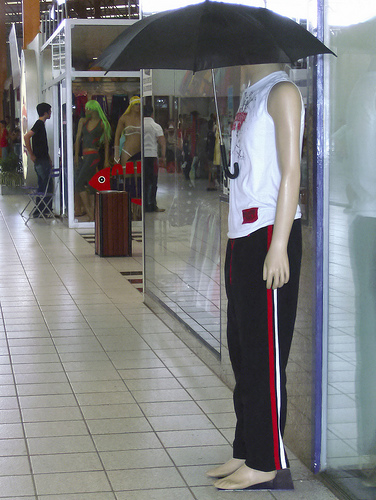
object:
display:
[245, 467, 294, 490]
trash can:
[89, 185, 135, 260]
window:
[61, 102, 68, 217]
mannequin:
[75, 100, 112, 222]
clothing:
[76, 116, 105, 195]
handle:
[220, 144, 239, 179]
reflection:
[144, 106, 165, 211]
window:
[139, 58, 242, 366]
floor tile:
[75, 391, 136, 404]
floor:
[0, 187, 349, 499]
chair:
[20, 166, 61, 225]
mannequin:
[208, 65, 308, 495]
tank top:
[225, 69, 306, 239]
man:
[23, 102, 52, 214]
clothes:
[31, 119, 54, 214]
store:
[147, 0, 375, 478]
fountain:
[93, 188, 131, 257]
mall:
[0, 0, 376, 499]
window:
[71, 77, 141, 223]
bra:
[123, 126, 141, 136]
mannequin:
[113, 96, 144, 212]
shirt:
[31, 119, 49, 160]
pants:
[224, 210, 302, 472]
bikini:
[119, 125, 141, 157]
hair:
[85, 100, 112, 144]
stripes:
[264, 222, 290, 474]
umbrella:
[95, 0, 337, 180]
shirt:
[227, 70, 304, 239]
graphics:
[88, 160, 142, 205]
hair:
[122, 95, 140, 115]